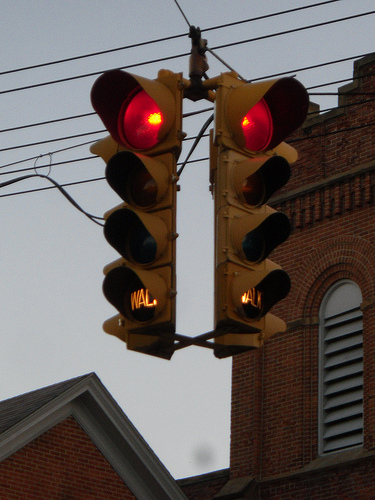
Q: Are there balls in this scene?
A: No, there are no balls.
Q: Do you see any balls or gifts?
A: No, there are no balls or gifts.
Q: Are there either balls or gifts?
A: No, there are no balls or gifts.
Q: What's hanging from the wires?
A: The traffic lights are hanging from the wires.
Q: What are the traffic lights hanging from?
A: The traffic lights are hanging from the wires.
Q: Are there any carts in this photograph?
A: No, there are no carts.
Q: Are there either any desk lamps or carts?
A: No, there are no carts or desk lamps.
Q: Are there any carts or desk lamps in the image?
A: No, there are no carts or desk lamps.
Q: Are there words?
A: Yes, there are words.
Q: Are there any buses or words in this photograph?
A: Yes, there are words.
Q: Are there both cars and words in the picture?
A: No, there are words but no cars.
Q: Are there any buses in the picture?
A: No, there are no buses.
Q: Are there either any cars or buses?
A: No, there are no buses or cars.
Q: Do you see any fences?
A: No, there are no fences.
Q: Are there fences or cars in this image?
A: No, there are no fences or cars.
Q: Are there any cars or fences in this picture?
A: No, there are no fences or cars.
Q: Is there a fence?
A: No, there are no fences.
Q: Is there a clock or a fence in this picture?
A: No, there are no fences or clocks.